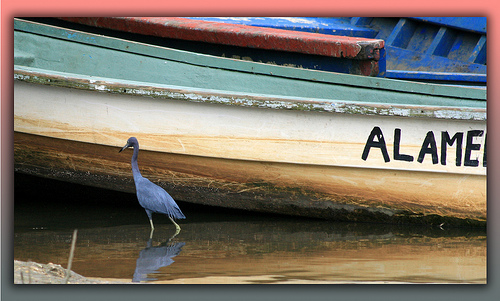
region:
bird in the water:
[117, 131, 196, 242]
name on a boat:
[353, 120, 487, 188]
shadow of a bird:
[123, 239, 187, 280]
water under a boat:
[233, 234, 468, 276]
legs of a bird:
[143, 214, 187, 245]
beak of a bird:
[111, 140, 128, 161]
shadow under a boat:
[24, 195, 119, 234]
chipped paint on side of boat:
[68, 70, 248, 117]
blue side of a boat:
[380, 23, 477, 91]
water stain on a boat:
[185, 132, 249, 153]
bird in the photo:
[101, 131, 186, 239]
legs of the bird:
[130, 216, 191, 248]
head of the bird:
[108, 126, 151, 163]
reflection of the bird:
[103, 248, 176, 290]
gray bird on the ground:
[103, 121, 191, 232]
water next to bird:
[183, 253, 239, 284]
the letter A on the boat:
[360, 125, 397, 181]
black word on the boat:
[346, 116, 492, 193]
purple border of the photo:
[68, 0, 155, 22]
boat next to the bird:
[36, 37, 422, 167]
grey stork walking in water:
[122, 126, 177, 243]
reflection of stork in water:
[121, 230, 186, 281]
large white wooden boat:
[24, 58, 482, 220]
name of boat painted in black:
[352, 117, 489, 172]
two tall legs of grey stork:
[139, 206, 184, 251]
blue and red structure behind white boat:
[227, 23, 484, 55]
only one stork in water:
[85, 105, 277, 249]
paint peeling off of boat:
[32, 68, 482, 125]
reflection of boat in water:
[24, 208, 439, 262]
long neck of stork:
[125, 145, 148, 182]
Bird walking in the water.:
[112, 135, 194, 255]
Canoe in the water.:
[17, 22, 492, 229]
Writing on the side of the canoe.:
[366, 125, 481, 178]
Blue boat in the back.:
[382, 18, 482, 77]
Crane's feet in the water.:
[143, 220, 184, 247]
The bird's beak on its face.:
[117, 141, 128, 155]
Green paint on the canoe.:
[34, 28, 124, 71]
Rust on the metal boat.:
[145, 15, 402, 79]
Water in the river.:
[83, 243, 390, 280]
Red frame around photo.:
[234, 0, 498, 15]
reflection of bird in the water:
[126, 241, 189, 281]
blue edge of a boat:
[359, 18, 486, 92]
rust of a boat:
[17, 119, 105, 151]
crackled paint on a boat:
[167, 75, 294, 117]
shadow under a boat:
[17, 172, 127, 224]